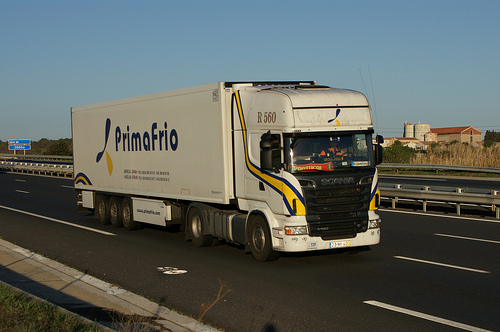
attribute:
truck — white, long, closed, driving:
[62, 77, 391, 263]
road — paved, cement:
[2, 170, 500, 330]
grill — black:
[299, 176, 374, 238]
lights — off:
[277, 220, 386, 233]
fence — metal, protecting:
[1, 152, 498, 217]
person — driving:
[311, 141, 353, 158]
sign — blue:
[5, 136, 37, 153]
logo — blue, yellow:
[88, 115, 197, 182]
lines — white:
[345, 212, 499, 331]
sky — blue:
[1, 2, 499, 144]